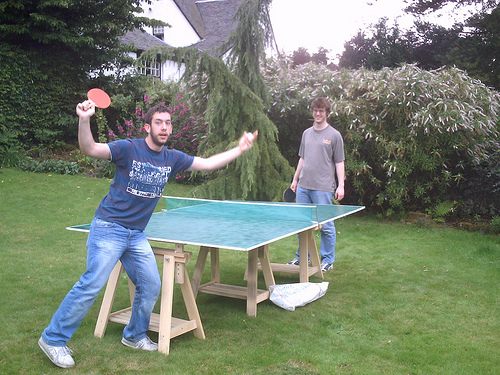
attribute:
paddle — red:
[81, 83, 114, 118]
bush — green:
[99, 77, 218, 192]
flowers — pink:
[168, 94, 193, 122]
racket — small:
[86, 85, 113, 114]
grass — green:
[364, 242, 487, 369]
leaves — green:
[6, 5, 66, 110]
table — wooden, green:
[50, 191, 375, 358]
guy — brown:
[284, 87, 356, 283]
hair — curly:
[302, 87, 336, 116]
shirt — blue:
[92, 134, 202, 234]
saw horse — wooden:
[88, 240, 217, 358]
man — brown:
[290, 93, 355, 280]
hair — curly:
[304, 91, 331, 112]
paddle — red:
[84, 82, 113, 114]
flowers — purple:
[137, 71, 209, 105]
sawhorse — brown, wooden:
[81, 260, 215, 361]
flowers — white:
[252, 49, 499, 132]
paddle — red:
[82, 86, 111, 112]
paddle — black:
[281, 186, 298, 203]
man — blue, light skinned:
[35, 97, 260, 369]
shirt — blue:
[92, 134, 192, 233]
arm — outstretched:
[75, 115, 127, 165]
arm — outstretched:
[174, 144, 240, 172]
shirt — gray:
[295, 121, 345, 191]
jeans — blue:
[291, 183, 337, 263]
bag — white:
[267, 278, 330, 312]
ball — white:
[244, 130, 254, 140]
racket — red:
[80, 86, 110, 112]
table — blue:
[63, 200, 365, 356]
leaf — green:
[46, 107, 50, 114]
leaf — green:
[29, 78, 35, 83]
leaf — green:
[5, 87, 10, 91]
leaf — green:
[26, 60, 31, 64]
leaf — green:
[56, 66, 58, 69]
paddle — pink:
[81, 87, 111, 111]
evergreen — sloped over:
[130, 46, 297, 201]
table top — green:
[64, 200, 366, 254]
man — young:
[289, 94, 346, 272]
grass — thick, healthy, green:
[1, 168, 483, 373]